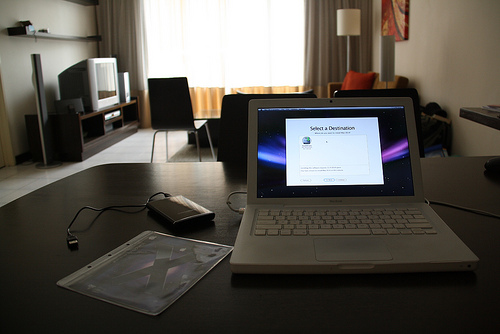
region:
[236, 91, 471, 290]
A laptop computer open and turned on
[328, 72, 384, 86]
An orange chair in the room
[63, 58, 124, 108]
An old style television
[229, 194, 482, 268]
The laptop keyboard is white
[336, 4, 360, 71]
A metal floor lamp with a white shade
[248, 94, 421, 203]
The laptop is turned on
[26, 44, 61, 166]
A tall surround sound speaker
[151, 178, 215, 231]
A portable hard drive on the desk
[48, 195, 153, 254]
Cord to the portable hard drive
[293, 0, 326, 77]
Tan colored drapes in the room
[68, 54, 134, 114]
television on the stand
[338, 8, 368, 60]
lamp in the corner of room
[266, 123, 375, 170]
laptop screen is on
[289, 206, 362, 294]
laptop on the table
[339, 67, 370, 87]
red pillow on the chair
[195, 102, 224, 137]
table in the middle of furniture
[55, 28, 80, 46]
shelf above the television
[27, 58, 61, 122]
speaker on side of stand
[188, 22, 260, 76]
light coming through the window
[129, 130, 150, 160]
white tile on the floor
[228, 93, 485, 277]
laptop with an open window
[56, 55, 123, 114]
television set powered off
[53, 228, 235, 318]
page protector with a sheet that has a big X on it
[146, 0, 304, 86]
sunlight shining through a window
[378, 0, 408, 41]
warm-colored painting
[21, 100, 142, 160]
dark wooden entertainment center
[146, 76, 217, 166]
black chair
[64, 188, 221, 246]
external hardrive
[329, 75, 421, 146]
cloth loveseat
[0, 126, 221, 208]
white tile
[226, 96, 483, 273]
gray laptop image on the screen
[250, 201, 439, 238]
gray keyboard on a laptop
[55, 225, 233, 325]
clear plastic presentation folder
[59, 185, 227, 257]
black external hard drive with a USB cord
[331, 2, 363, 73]
white lamp with a skinny pole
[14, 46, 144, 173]
entertainment center with a older television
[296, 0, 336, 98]
neutral colored curtains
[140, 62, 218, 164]
office chair seen from behind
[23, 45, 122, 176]
tall speaker next to a television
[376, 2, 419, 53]
lower half of a colorful painting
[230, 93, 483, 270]
Laptop computer powered on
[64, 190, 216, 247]
External hard drive and cord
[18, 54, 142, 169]
Entertainment center with television and speakers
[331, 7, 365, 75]
Floor lamp by some curtains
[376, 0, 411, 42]
Painting on a wall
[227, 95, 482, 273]
Laptop computer sitting on a table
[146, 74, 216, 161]
Hard chair with metal legs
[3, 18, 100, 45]
Shelf on the wall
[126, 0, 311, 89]
Light coming through curtains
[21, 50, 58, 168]
Speaker on a metal stand